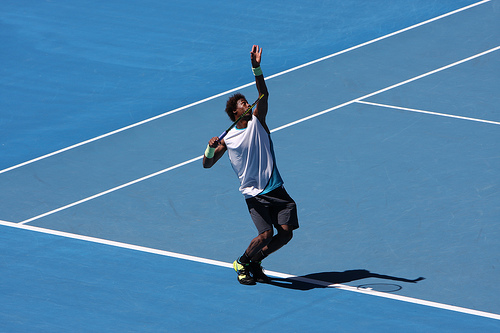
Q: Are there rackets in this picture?
A: Yes, there is a racket.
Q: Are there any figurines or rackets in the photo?
A: Yes, there is a racket.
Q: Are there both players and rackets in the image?
A: Yes, there are both a racket and a player.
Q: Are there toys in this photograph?
A: No, there are no toys.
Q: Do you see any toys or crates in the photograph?
A: No, there are no toys or crates.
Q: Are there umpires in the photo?
A: No, there are no umpires.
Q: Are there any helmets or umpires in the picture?
A: No, there are no umpires or helmets.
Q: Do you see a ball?
A: No, there are no balls.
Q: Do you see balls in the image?
A: No, there are no balls.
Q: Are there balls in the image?
A: No, there are no balls.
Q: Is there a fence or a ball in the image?
A: No, there are no balls or fences.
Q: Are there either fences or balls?
A: No, there are no balls or fences.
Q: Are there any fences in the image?
A: No, there are no fences.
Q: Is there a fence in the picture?
A: No, there are no fences.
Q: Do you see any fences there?
A: No, there are no fences.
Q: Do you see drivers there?
A: No, there are no drivers.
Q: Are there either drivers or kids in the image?
A: No, there are no drivers or kids.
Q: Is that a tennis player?
A: Yes, that is a tennis player.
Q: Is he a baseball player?
A: No, that is a tennis player.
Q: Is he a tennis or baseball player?
A: That is a tennis player.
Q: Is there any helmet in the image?
A: No, there are no helmets.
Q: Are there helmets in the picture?
A: No, there are no helmets.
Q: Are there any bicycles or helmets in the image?
A: No, there are no helmets or bicycles.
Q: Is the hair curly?
A: Yes, the hair is curly.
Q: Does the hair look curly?
A: Yes, the hair is curly.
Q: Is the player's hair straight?
A: No, the hair is curly.